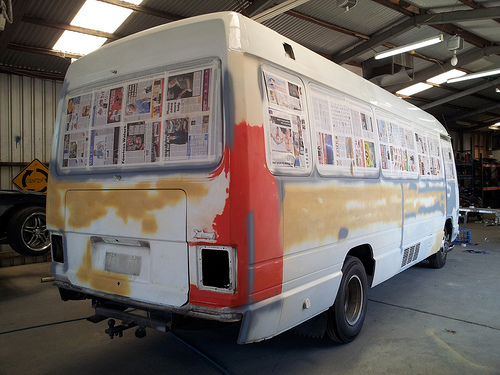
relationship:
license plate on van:
[100, 249, 144, 276] [42, 9, 460, 343]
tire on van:
[318, 253, 371, 345] [42, 9, 460, 343]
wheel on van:
[328, 251, 370, 347] [42, 9, 460, 343]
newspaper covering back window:
[68, 95, 204, 152] [50, 59, 224, 178]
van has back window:
[42, 9, 460, 343] [50, 59, 224, 178]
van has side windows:
[42, 9, 460, 343] [249, 62, 448, 182]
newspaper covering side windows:
[265, 74, 446, 177] [249, 62, 448, 182]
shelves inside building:
[455, 148, 500, 204] [1, 0, 500, 375]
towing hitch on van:
[101, 315, 126, 341] [42, 9, 460, 343]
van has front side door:
[42, 9, 460, 343] [437, 134, 458, 227]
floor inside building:
[8, 219, 497, 375] [1, 0, 500, 375]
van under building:
[42, 9, 460, 343] [1, 0, 500, 375]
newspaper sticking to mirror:
[68, 95, 204, 152] [55, 62, 223, 173]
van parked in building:
[42, 9, 460, 343] [1, 0, 500, 375]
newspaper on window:
[68, 95, 204, 152] [53, 57, 222, 169]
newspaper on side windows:
[265, 74, 446, 177] [255, 62, 312, 179]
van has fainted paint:
[42, 9, 460, 343] [47, 170, 458, 302]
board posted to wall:
[12, 155, 48, 194] [3, 74, 62, 191]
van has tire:
[42, 9, 460, 343] [318, 253, 371, 345]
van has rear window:
[42, 9, 460, 343] [56, 61, 220, 173]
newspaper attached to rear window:
[68, 95, 204, 152] [56, 61, 220, 173]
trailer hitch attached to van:
[89, 301, 175, 342] [42, 9, 460, 343]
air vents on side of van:
[398, 240, 423, 268] [42, 9, 460, 343]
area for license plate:
[90, 237, 151, 282] [100, 249, 144, 276]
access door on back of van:
[59, 185, 197, 309] [42, 9, 460, 343]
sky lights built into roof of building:
[396, 62, 465, 110] [1, 0, 500, 375]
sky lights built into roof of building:
[52, 0, 141, 72] [1, 0, 500, 375]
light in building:
[373, 32, 447, 60] [1, 0, 500, 375]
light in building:
[446, 62, 499, 87] [1, 0, 500, 375]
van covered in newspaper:
[42, 9, 460, 343] [68, 95, 204, 152]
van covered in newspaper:
[42, 9, 460, 343] [265, 74, 446, 177]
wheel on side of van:
[328, 251, 370, 347] [42, 9, 460, 343]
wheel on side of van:
[427, 227, 450, 269] [42, 9, 460, 343]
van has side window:
[42, 9, 460, 343] [311, 87, 382, 179]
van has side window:
[42, 9, 460, 343] [376, 114, 420, 180]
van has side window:
[42, 9, 460, 343] [413, 130, 445, 181]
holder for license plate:
[91, 237, 153, 279] [100, 249, 144, 276]